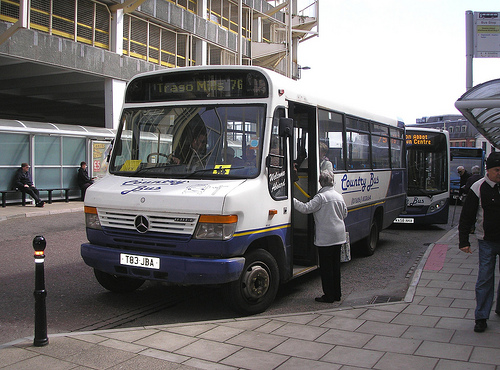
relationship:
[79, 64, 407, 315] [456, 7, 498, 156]
bus at stop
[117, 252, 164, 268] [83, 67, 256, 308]
license plate on front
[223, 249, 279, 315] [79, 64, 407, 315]
tire on bus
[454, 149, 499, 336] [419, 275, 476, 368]
man on sidewalk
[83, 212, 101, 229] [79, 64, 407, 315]
light on bus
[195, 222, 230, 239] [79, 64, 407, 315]
light on bus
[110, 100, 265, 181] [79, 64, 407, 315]
front window on bus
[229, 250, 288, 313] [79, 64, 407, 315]
tire on bus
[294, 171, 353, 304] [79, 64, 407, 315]
woman on bus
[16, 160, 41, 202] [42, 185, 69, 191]
man on bench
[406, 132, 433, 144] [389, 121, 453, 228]
sign on bus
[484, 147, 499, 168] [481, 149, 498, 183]
cap on head head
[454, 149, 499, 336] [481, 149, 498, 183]
man has head